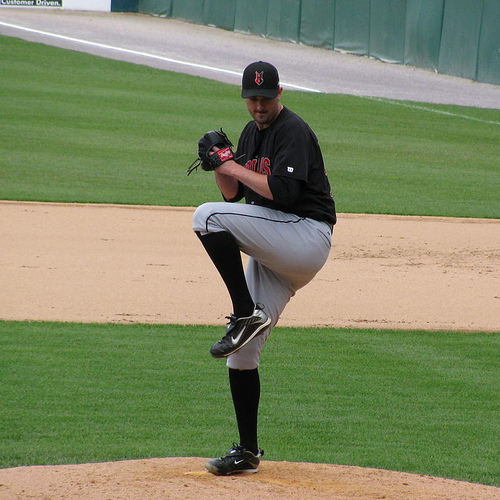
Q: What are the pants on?
A: The pants are on the mound.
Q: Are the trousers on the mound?
A: Yes, the trousers are on the mound.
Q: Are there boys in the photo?
A: No, there are no boys.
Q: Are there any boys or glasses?
A: No, there are no boys or glasses.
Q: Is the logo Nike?
A: Yes, the logo is nike.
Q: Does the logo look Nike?
A: Yes, the logo is nike.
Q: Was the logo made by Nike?
A: Yes, the logo was made by nike.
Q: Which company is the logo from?
A: The logo is from nike.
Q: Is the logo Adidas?
A: No, the logo is nike.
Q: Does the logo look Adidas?
A: No, the logo is nike.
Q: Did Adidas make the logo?
A: No, the logo was made by nike.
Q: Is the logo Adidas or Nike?
A: The logo is nike.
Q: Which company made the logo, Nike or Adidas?
A: The logo was made nike.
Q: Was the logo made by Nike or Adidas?
A: The logo was made nike.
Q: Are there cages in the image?
A: No, there are no cages.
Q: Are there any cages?
A: No, there are no cages.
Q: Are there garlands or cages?
A: No, there are no cages or garlands.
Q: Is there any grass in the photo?
A: Yes, there is grass.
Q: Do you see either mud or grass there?
A: Yes, there is grass.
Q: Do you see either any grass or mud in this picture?
A: Yes, there is grass.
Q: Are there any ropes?
A: No, there are no ropes.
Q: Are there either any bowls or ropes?
A: No, there are no ropes or bowls.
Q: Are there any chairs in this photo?
A: No, there are no chairs.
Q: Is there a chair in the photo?
A: No, there are no chairs.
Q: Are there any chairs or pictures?
A: No, there are no chairs or pictures.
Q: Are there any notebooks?
A: No, there are no notebooks.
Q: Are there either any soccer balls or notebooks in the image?
A: No, there are no notebooks or soccer balls.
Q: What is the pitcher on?
A: The pitcher is on the mound.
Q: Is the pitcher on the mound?
A: Yes, the pitcher is on the mound.